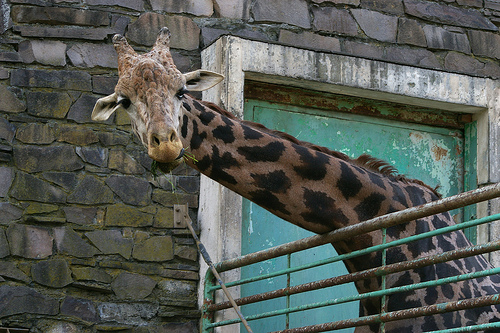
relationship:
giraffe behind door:
[77, 30, 496, 328] [239, 70, 500, 333]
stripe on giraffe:
[291, 142, 331, 179] [77, 30, 496, 328]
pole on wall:
[180, 206, 251, 331] [2, 2, 199, 332]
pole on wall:
[180, 206, 251, 331] [200, 0, 498, 80]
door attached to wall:
[239, 70, 500, 333] [3, 0, 498, 332]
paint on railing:
[378, 269, 498, 285] [200, 178, 498, 332]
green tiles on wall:
[104, 202, 178, 223] [22, 82, 81, 298]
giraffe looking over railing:
[77, 30, 496, 328] [181, 184, 497, 331]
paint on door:
[236, 93, 479, 328] [208, 45, 496, 329]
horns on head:
[114, 25, 173, 63] [95, 29, 228, 166]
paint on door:
[258, 221, 262, 225] [244, 91, 472, 331]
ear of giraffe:
[169, 55, 239, 93] [77, 30, 496, 328]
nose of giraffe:
[136, 127, 186, 162] [77, 30, 496, 328]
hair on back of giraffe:
[290, 130, 398, 181] [77, 30, 496, 328]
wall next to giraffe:
[3, 0, 498, 332] [77, 30, 496, 328]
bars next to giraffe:
[216, 257, 451, 330] [77, 30, 496, 328]